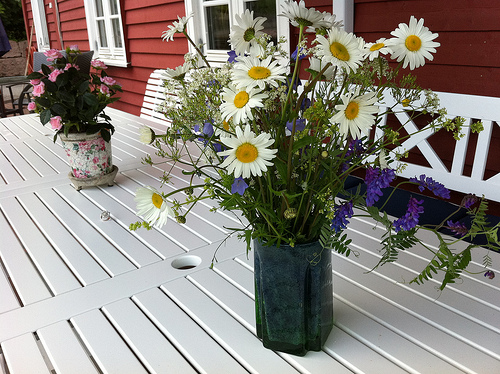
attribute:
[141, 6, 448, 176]
daisies — white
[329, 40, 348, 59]
center — yellow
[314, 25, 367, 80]
daisy — white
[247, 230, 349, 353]
vase — tall, glass, blue, round, blue green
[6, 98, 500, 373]
table — white, picket style, long, wood slat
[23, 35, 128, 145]
roses — pink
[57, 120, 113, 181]
planter — pink, white, floral, flower patterned, mosaic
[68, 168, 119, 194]
stand — four legged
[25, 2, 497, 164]
wall — red, paneled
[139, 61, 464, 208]
bench — white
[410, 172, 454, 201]
flower — purple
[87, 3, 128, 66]
window — paned, small, white, framed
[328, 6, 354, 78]
rain gutter — white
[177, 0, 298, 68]
frame — white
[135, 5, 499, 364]
bouquet — flowers, daisies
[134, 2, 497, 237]
flowers — purple, cone-shaped